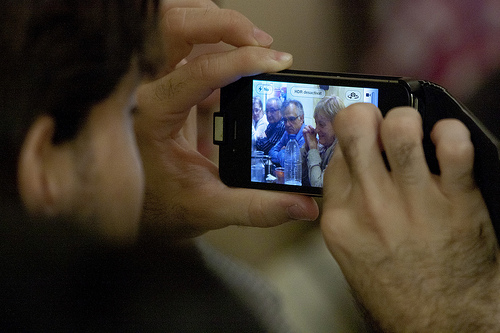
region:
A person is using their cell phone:
[8, 8, 494, 313]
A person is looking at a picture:
[11, 22, 466, 282]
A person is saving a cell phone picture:
[5, 5, 490, 316]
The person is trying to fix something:
[10, 10, 495, 318]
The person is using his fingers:
[0, 22, 490, 314]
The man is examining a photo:
[3, 21, 474, 321]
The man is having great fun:
[6, 15, 496, 290]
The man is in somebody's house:
[7, 18, 494, 304]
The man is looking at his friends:
[5, 16, 481, 317]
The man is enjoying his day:
[19, 20, 498, 302]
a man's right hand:
[316, 104, 497, 329]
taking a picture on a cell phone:
[216, 67, 421, 196]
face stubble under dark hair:
[67, 116, 106, 258]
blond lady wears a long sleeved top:
[300, 91, 335, 191]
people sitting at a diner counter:
[251, 86, 335, 187]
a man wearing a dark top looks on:
[254, 95, 284, 155]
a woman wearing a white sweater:
[251, 94, 268, 146]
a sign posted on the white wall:
[295, 84, 327, 101]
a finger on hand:
[435, 102, 484, 187]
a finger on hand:
[379, 108, 429, 204]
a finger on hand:
[329, 116, 407, 201]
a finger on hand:
[315, 146, 357, 196]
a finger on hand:
[224, 189, 337, 233]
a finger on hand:
[149, 19, 274, 81]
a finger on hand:
[189, 8, 299, 58]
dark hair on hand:
[394, 139, 429, 204]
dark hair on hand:
[457, 170, 477, 208]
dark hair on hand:
[443, 219, 493, 277]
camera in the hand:
[224, 68, 471, 222]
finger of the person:
[419, 108, 474, 183]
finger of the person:
[369, 108, 433, 183]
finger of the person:
[343, 114, 392, 180]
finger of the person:
[324, 163, 349, 220]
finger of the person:
[247, 185, 314, 232]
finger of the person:
[234, 45, 283, 71]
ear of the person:
[21, 120, 66, 214]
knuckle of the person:
[320, 211, 345, 252]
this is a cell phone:
[217, 80, 327, 247]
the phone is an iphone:
[232, 79, 342, 199]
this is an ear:
[6, 90, 48, 237]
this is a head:
[77, 77, 177, 296]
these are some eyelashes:
[112, 57, 149, 217]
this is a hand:
[154, 129, 274, 304]